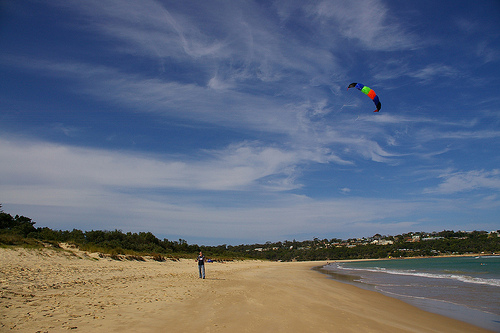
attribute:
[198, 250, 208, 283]
person — flying, walking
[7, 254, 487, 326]
beach — sandy, here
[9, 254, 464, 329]
sand — brown, beach's, tan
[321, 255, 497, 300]
wave — white, approaching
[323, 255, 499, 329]
ocean — blue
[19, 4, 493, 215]
clouds — white, wispy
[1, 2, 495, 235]
sky — blue, cloudy, here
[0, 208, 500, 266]
trees — green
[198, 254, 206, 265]
shirt — blue, dark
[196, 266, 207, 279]
jeans — man's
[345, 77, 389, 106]
kite — multi colored, multi-colored, flying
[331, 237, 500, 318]
water — ocean's, here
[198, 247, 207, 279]
man — flying, using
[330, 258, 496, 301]
waves — rolling, ocean's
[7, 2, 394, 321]
side — beach's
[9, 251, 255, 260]
area — grassy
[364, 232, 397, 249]
building — big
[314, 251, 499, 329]
edge — shore's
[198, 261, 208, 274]
trouser — here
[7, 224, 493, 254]
forest — here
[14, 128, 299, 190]
cloud — here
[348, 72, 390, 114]
parachute — here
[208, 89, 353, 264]
string — kite's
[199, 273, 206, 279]
shoes — man's